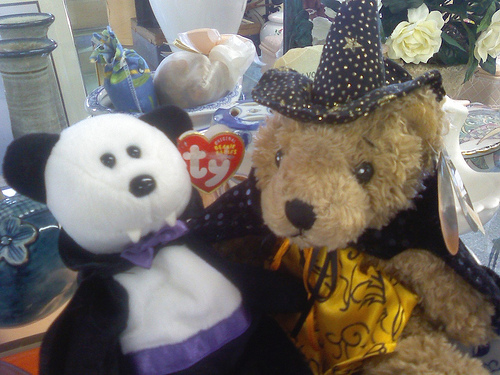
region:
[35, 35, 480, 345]
two stuffed animals next to each other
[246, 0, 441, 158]
the bear on the right is wearing a hat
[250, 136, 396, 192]
the eyes are black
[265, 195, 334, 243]
the nose is black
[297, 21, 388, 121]
the hat has stars on it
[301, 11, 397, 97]
the stars are gold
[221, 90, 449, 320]
the bear is tan colored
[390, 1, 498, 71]
white flowers behind the bear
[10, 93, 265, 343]
the bear on the left is black and white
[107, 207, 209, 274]
bear is wearing a purple tie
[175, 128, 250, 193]
Red heart tag with "ty" written in white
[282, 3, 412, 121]
Dark blue wizard hat with yellow stars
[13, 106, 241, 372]
Black and white stuffed bear in vampire costume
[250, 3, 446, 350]
Brown stuffed bear in wizard's costume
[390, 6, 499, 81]
Pale yellow flowers in teacup pot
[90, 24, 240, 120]
Gift bags in blue and white bowl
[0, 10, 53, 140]
Sandy white vases with blue rims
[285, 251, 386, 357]
Yellow silk cape with black swirly design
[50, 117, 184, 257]
Black and white stuffed bear with fangs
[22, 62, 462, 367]
Two stuffed animals in costumes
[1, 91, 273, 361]
beanie babie dressed up for halloween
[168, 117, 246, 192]
tag in bear's ear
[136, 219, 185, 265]
bow tie on bear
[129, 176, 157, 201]
nose on the bear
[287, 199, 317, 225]
nose on the bear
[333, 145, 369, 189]
eye of the bear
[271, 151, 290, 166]
eye of the bear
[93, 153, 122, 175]
eye of the bear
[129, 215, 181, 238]
fangs of the bear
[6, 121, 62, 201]
ear of the bear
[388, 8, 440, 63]
Small light yellow rose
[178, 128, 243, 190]
Red heart shape ty tag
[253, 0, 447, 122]
Gold and blue wizard hat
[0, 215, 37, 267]
Small blue and white flower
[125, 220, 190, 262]
Small purple bow tie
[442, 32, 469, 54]
Small thin green leaf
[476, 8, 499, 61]
Light yellow fake rose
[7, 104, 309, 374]
Black and white stuffed bear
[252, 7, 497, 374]
Soft brown teddy bear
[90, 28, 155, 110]
Tied small blue cloth bag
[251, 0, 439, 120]
pointy hat on bears head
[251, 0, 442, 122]
hat covering in gold stars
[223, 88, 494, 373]
brown stuff bear with cape on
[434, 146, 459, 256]
tag hanging from bear's ear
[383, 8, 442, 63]
white flower in the back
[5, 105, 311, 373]
black and white stuff toy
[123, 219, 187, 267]
purple bow tie around toy's neck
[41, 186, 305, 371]
black cape around toy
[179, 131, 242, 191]
red heart with t9 on it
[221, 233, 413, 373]
yellow and black material around bear